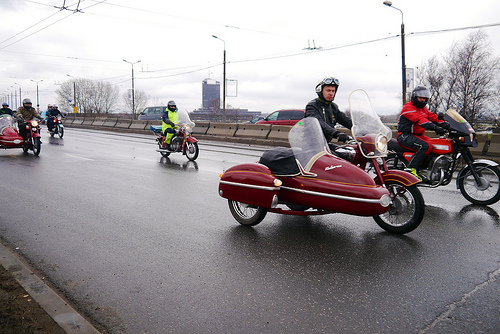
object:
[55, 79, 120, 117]
trees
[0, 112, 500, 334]
pavement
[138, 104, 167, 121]
car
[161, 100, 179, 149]
person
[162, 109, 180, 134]
yellow raincoat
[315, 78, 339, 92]
helmet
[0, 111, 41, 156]
bikes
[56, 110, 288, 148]
barrier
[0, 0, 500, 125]
sky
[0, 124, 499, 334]
road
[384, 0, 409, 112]
pole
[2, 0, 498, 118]
clouds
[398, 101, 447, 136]
jacket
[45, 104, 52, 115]
person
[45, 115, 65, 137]
bike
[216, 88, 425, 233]
bike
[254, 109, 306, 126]
car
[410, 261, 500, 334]
crack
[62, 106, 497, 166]
side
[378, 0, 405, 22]
light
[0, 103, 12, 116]
person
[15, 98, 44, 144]
person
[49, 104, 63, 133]
person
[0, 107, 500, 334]
street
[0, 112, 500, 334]
highway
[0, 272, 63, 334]
dirt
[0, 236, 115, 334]
side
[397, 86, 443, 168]
outfit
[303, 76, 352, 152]
person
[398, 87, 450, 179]
person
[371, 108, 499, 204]
bike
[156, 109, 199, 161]
bike